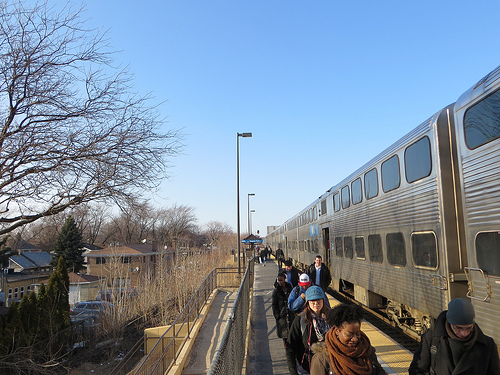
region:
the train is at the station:
[240, 157, 492, 327]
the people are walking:
[258, 197, 468, 373]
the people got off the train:
[256, 205, 465, 361]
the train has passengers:
[222, 149, 485, 341]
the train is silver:
[237, 155, 459, 296]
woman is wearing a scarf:
[316, 325, 377, 369]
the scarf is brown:
[315, 322, 377, 370]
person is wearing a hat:
[427, 288, 486, 352]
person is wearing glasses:
[442, 320, 477, 344]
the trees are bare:
[124, 238, 202, 319]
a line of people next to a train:
[264, 233, 485, 373]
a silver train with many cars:
[232, 135, 498, 345]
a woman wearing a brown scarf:
[313, 300, 387, 373]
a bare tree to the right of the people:
[0, 75, 182, 282]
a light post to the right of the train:
[213, 107, 258, 285]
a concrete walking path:
[136, 257, 264, 370]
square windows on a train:
[309, 70, 494, 337]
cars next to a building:
[7, 250, 129, 331]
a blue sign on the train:
[260, 189, 497, 328]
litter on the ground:
[51, 327, 158, 370]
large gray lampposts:
[235, 129, 265, 310]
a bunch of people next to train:
[250, 245, 485, 372]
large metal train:
[255, 51, 498, 356]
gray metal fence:
[133, 253, 255, 373]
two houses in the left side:
[2, 230, 148, 352]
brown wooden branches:
[0, 0, 180, 247]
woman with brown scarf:
[303, 301, 385, 372]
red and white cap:
[295, 270, 313, 287]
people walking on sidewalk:
[252, 242, 498, 372]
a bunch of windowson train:
[260, 83, 499, 279]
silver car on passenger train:
[315, 182, 445, 278]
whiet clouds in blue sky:
[117, 10, 169, 62]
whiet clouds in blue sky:
[150, 55, 185, 100]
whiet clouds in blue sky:
[188, 140, 230, 193]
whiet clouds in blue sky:
[279, 160, 308, 196]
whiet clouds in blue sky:
[267, 81, 309, 142]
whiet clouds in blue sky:
[161, 30, 229, 85]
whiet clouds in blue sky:
[332, 48, 380, 105]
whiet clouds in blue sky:
[237, 21, 320, 63]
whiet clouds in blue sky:
[378, 30, 450, 68]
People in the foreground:
[289, 291, 498, 373]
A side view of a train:
[255, 55, 499, 336]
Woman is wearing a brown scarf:
[320, 325, 375, 373]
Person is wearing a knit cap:
[441, 291, 477, 332]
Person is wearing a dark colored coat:
[406, 313, 499, 373]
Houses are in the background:
[0, 226, 206, 332]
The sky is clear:
[4, 2, 496, 222]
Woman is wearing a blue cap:
[296, 283, 331, 310]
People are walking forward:
[260, 248, 498, 373]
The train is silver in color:
[260, 64, 499, 350]